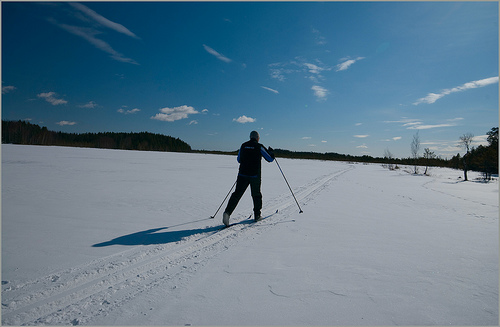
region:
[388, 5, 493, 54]
The sky is blue.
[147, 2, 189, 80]
The sky is clear.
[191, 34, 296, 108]
The clouds are white.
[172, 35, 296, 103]
A few clouds are in the sky.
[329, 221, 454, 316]
Snow is on the ground.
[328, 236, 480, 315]
The snow is white.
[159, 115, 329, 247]
A skier skiing.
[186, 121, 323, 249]
The person is in the snow.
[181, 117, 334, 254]
The person is skiing.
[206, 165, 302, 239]
The person is wearing black pants.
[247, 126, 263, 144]
the head of a man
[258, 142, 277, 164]
the arm of a man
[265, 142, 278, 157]
the hand of a man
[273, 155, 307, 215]
a ski pole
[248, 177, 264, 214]
the leg of a man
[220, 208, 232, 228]
a white ski boot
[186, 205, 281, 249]
a pair of skis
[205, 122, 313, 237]
a man skiing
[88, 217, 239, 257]
a shadow on the ground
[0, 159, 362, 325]
white ski tracks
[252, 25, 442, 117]
clear light blue sky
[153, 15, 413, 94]
clear light blue sky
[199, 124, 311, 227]
a man riding skis.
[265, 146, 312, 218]
a long right ski pole.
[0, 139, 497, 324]
snow covered ski slope.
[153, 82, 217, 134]
a cloud in a blue sky.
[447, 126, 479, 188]
a leafless tree in the snow.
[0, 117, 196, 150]
a hill covered in trees.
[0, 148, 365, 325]
tracks in the snow.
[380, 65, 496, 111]
A long thin cloud.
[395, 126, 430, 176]
A tree with no leaves.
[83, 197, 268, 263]
a shadow cast in the snow.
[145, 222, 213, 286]
ski tracks in snow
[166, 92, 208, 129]
white fluffy clouds in sky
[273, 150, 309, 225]
right ski poles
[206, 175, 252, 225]
left ski pole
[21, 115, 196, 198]
mass of trees on left side of photo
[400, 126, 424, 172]
winter tree with no leaves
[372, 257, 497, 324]
drifted over snow pattern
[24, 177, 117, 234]
white expanse of snow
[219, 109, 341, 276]
man skiing in snow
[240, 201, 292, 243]
ski on man's right foot